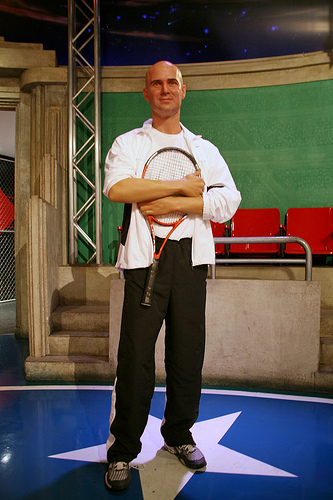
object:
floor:
[0, 382, 333, 498]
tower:
[66, 3, 101, 266]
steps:
[30, 257, 118, 377]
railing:
[66, 0, 102, 267]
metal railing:
[209, 235, 313, 282]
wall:
[206, 264, 323, 389]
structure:
[0, 0, 333, 500]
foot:
[163, 438, 207, 473]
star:
[44, 406, 301, 498]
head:
[142, 60, 187, 119]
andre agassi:
[103, 61, 243, 493]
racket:
[140, 147, 200, 307]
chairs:
[116, 207, 333, 265]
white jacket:
[103, 116, 243, 274]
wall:
[77, 81, 333, 265]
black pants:
[106, 233, 207, 466]